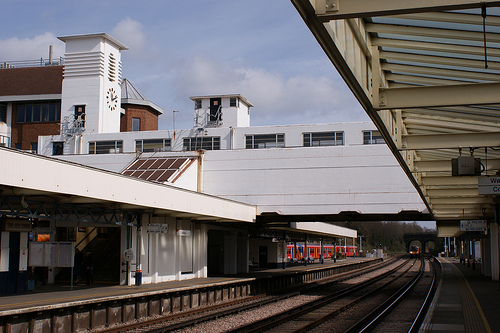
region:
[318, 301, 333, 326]
The railroad tracks are a deep brown color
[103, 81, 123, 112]
There is a clock on the old white tower in the city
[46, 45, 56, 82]
There is a smokestack on the upper deck for letting out exhaust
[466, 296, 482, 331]
There is a yellow line on the side of the tracks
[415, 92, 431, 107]
There is a cream-colored beam above the track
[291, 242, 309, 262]
There are red-colored trolley cars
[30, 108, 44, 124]
There are blackened windows in the tower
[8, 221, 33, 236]
There is a sign in the interior of the station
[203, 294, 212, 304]
There is brown rust on the side of the tracks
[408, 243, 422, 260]
There is a train currently coming into the station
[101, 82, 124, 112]
black and white clock in tower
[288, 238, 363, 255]
red cars of train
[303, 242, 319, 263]
black windows of red train car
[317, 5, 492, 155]
gray support at train station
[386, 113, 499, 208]
gray support at train station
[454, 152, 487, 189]
black and white sign at train station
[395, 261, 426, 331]
silver tracks at train station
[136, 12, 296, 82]
white clouds against blue sky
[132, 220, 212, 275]
gray wall on platform at train station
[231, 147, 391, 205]
white wall above platform at train station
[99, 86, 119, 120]
clock on white tower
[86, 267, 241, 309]
platform at train station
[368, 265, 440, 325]
train tracks at station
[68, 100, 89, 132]
door on station tower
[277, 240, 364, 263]
red train at station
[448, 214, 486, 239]
sign over train platform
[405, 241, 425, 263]
train in the distance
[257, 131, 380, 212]
walkway over train tracks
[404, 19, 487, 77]
skylights over train platform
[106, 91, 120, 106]
hands on tower clock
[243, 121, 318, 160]
window in white building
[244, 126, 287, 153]
lines in white window panes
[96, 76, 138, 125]
round clock on white wall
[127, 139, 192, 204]
slanted dark red roof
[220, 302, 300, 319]
small stones in middle of track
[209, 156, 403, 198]
large thin lines on side of building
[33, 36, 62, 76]
tall stack on top of building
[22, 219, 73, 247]
light on the platform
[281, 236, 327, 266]
blue spot on the platform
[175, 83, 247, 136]
steps leading up to the top of the building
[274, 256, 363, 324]
long shadow on track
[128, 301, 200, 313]
lines in edge of platform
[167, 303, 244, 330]
brown train tracks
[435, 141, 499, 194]
overhead sign in platform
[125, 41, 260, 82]
blue and white skies overhead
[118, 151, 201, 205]
slanted red roof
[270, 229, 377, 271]
red doors on train platform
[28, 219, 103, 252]
windows on the platform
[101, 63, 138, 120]
white clock on top of building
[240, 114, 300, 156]
lines in the windows